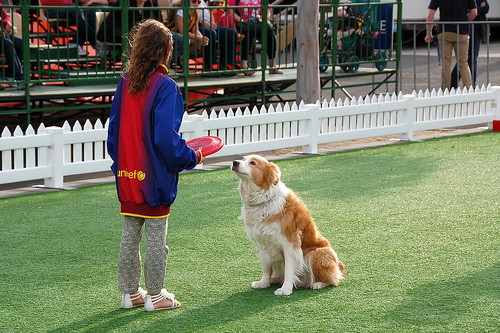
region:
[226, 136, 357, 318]
The dog is sitting.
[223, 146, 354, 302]
The dog is alert.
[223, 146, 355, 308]
The dog is brown and white.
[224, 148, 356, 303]
The dog is long haired.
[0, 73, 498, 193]
The fence is white.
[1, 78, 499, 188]
The fence is wood.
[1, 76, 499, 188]
The fence pickets are pointed.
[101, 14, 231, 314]
The woman is holding a frisbee.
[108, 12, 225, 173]
The frisbee is red.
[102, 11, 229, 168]
The woman's hair is windblown.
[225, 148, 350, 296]
Brown and white dog sitting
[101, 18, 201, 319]
A girl standing on grass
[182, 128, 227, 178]
A red frisbee with writing on it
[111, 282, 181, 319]
White strappy sandals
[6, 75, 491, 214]
Low white picket style fence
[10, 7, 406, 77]
Green metal barrier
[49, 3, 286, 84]
A group of people sitting and watching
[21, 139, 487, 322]
Green grass inside a white fence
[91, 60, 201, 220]
Red, blue and yellow sports jersey top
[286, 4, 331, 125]
A thick wooden post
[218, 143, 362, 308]
this is a dog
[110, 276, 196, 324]
these are the shoes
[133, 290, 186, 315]
this is a shoe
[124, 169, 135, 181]
this is the letter E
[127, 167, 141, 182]
this is the letter F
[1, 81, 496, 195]
this is a fence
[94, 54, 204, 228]
this is a jacket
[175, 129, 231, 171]
this is a frisbee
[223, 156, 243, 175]
this is a dog nose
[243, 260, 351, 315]
these are dog paws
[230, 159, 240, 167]
A dogs black nose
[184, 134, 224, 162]
A person holding frisbee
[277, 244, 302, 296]
A dogs white leg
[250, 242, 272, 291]
A dogs right leg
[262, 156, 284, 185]
A dogs brown ear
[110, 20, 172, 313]
A perosn with brown hair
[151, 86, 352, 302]
Dog looking at frisbee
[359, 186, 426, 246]
Green grassy astro turf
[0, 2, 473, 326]
Event at dog competition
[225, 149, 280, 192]
A brown and white dog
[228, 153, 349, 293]
dog is ready to follow commands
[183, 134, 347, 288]
dog is very interested in the frisbee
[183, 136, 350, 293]
dog looks eager to perform a trick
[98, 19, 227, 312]
girl is holding a frisbee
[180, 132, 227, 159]
this frisbee is red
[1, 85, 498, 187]
white picket fence borders the show area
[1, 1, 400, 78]
spectators watching a dog and its handler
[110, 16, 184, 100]
the wind is blowing this girl's hair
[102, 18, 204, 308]
girl is wearing a jacket too big for her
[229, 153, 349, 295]
this dog is brown and white with gentle eyes